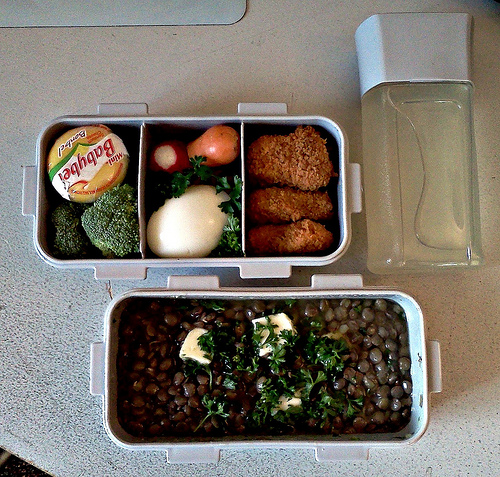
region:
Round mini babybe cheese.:
[46, 125, 131, 200]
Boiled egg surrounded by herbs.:
[144, 177, 239, 256]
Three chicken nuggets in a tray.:
[246, 122, 339, 256]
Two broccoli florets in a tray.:
[42, 194, 142, 259]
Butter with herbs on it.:
[182, 312, 302, 414]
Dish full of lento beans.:
[90, 275, 441, 449]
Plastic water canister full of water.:
[360, 7, 490, 275]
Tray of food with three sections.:
[21, 101, 360, 276]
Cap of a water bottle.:
[350, 7, 476, 94]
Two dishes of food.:
[19, 100, 441, 469]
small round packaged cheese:
[46, 121, 128, 203]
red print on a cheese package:
[103, 151, 123, 166]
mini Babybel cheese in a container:
[46, 121, 130, 203]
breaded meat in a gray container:
[247, 123, 334, 190]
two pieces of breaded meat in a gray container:
[245, 122, 335, 222]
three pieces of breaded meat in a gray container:
[241, 120, 339, 256]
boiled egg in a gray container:
[145, 181, 232, 256]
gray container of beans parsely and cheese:
[117, 296, 418, 438]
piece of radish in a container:
[147, 144, 189, 174]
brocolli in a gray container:
[79, 182, 141, 256]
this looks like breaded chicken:
[246, 124, 336, 256]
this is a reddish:
[146, 134, 196, 179]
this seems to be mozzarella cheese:
[146, 180, 237, 257]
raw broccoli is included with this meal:
[49, 183, 136, 259]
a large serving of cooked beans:
[101, 288, 436, 455]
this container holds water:
[338, 8, 494, 284]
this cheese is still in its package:
[43, 121, 133, 204]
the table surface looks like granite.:
[4, 31, 495, 471]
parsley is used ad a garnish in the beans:
[177, 300, 365, 436]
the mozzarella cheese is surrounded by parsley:
[147, 144, 241, 259]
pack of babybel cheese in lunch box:
[35, 123, 144, 216]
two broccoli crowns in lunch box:
[42, 188, 146, 265]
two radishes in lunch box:
[140, 119, 251, 194]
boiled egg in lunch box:
[134, 175, 248, 256]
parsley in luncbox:
[147, 136, 272, 258]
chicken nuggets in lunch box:
[253, 123, 351, 261]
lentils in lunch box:
[123, 293, 440, 450]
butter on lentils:
[157, 307, 342, 367]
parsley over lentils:
[166, 324, 381, 421]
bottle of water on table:
[342, 13, 498, 309]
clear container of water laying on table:
[352, 6, 487, 273]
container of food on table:
[21, 95, 363, 275]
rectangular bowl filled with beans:
[88, 277, 444, 464]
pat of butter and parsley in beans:
[248, 310, 302, 363]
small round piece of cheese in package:
[45, 124, 129, 202]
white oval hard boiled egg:
[145, 179, 233, 257]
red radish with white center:
[148, 137, 189, 171]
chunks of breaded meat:
[250, 125, 335, 250]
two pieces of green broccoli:
[50, 185, 137, 256]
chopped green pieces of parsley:
[311, 336, 348, 367]